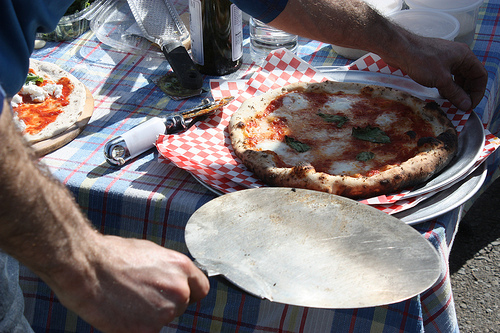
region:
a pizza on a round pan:
[199, 42, 481, 200]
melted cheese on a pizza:
[267, 84, 326, 121]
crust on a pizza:
[390, 123, 469, 190]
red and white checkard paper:
[192, 49, 325, 153]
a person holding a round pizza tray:
[92, 206, 402, 318]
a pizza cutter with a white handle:
[102, 83, 240, 169]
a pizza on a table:
[188, 97, 490, 214]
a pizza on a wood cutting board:
[22, 64, 99, 159]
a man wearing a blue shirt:
[0, 4, 66, 145]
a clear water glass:
[242, 25, 298, 61]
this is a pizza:
[232, 84, 432, 174]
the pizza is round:
[230, 79, 442, 181]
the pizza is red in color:
[292, 100, 378, 160]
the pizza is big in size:
[256, 86, 423, 178]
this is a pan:
[240, 204, 365, 281]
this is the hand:
[74, 235, 151, 310]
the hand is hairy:
[11, 177, 62, 238]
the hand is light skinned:
[88, 246, 155, 306]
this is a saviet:
[175, 123, 220, 159]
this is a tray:
[468, 129, 482, 145]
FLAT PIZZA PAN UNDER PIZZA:
[156, 202, 424, 329]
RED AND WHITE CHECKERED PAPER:
[148, 66, 373, 200]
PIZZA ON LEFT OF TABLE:
[27, 58, 102, 146]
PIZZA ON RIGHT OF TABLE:
[218, 62, 416, 199]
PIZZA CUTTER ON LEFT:
[112, 80, 244, 164]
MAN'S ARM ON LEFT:
[0, 110, 190, 330]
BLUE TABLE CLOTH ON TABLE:
[57, 5, 495, 305]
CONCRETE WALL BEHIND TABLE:
[456, 199, 496, 273]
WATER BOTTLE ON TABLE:
[238, 12, 306, 68]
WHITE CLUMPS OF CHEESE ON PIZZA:
[27, 80, 82, 103]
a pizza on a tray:
[44, 34, 490, 305]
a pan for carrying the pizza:
[173, 176, 466, 321]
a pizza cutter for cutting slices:
[127, 75, 237, 185]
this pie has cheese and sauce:
[241, 41, 454, 187]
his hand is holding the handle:
[24, 199, 231, 328]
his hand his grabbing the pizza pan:
[358, 17, 498, 138]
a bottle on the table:
[182, 1, 264, 71]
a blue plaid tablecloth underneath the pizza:
[87, 35, 173, 119]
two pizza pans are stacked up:
[423, 114, 497, 227]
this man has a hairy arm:
[7, 117, 104, 297]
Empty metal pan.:
[176, 182, 441, 310]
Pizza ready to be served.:
[230, 75, 465, 197]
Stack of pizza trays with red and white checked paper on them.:
[168, 51, 492, 221]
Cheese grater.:
[128, 1, 208, 94]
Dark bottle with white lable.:
[188, 0, 244, 75]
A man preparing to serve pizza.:
[0, 0, 490, 332]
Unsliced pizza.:
[229, 78, 461, 196]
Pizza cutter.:
[105, 95, 235, 166]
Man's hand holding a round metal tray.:
[47, 180, 444, 331]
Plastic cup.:
[385, 5, 459, 41]